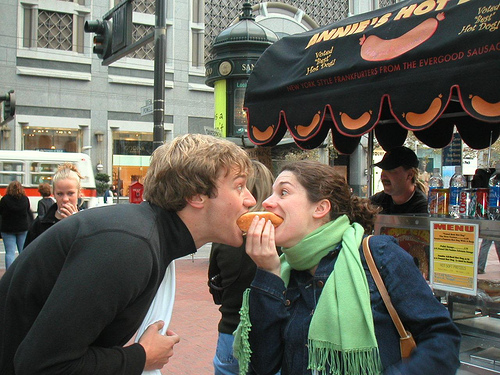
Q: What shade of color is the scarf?
A: Green.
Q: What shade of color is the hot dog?
A: Red.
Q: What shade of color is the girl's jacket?
A: Blue.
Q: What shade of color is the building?
A: Gray.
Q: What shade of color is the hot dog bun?
A: Brown.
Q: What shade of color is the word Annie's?
A: Yellow.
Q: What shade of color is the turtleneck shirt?
A: Black.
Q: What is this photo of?
A: Two people eating a hot dog.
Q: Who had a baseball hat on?
A: The man in background.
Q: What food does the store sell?
A: Hot dogs.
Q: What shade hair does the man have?
A: Blond.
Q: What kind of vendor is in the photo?
A: Hot dog vendor.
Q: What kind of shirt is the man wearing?
A: A turtleneck.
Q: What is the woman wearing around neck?
A: A scarf.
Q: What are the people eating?
A: Hot dog.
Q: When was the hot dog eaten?
A: Cloudy day.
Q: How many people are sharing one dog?
A: Two.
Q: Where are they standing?
A: In front of a hot dog stand.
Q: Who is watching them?
A: A girl.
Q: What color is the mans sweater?
A: Black.